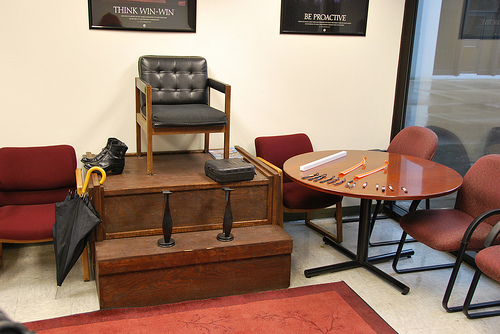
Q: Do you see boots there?
A: Yes, there are boots.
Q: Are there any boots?
A: Yes, there are boots.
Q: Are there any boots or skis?
A: Yes, there are boots.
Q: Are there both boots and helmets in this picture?
A: No, there are boots but no helmets.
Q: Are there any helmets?
A: No, there are no helmets.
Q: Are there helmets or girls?
A: No, there are no helmets or girls.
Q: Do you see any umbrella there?
A: Yes, there is an umbrella.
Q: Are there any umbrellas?
A: Yes, there is an umbrella.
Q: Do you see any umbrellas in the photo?
A: Yes, there is an umbrella.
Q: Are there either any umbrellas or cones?
A: Yes, there is an umbrella.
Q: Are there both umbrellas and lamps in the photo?
A: No, there is an umbrella but no lamps.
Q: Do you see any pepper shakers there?
A: No, there are no pepper shakers.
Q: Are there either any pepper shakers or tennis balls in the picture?
A: No, there are no pepper shakers or tennis balls.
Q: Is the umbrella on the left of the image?
A: Yes, the umbrella is on the left of the image.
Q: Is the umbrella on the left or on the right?
A: The umbrella is on the left of the image.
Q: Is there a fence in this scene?
A: No, there are no fences.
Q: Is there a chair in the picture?
A: Yes, there is a chair.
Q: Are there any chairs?
A: Yes, there is a chair.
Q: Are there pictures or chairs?
A: Yes, there is a chair.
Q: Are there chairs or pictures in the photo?
A: Yes, there is a chair.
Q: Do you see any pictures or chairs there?
A: Yes, there is a chair.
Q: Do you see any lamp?
A: No, there are no lamps.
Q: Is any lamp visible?
A: No, there are no lamps.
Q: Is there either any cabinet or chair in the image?
A: Yes, there is a chair.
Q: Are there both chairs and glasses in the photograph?
A: No, there is a chair but no glasses.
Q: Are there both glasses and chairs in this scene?
A: No, there is a chair but no glasses.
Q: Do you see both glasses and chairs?
A: No, there is a chair but no glasses.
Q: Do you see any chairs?
A: Yes, there is a chair.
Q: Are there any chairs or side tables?
A: Yes, there is a chair.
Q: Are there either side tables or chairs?
A: Yes, there is a chair.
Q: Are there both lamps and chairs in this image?
A: No, there is a chair but no lamps.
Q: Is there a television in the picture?
A: No, there are no televisions.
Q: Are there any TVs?
A: No, there are no tvs.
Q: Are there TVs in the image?
A: No, there are no tvs.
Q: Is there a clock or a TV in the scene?
A: No, there are no televisions or clocks.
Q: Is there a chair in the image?
A: Yes, there is a chair.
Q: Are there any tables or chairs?
A: Yes, there is a chair.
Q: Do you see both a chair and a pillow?
A: No, there is a chair but no pillows.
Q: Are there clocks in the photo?
A: No, there are no clocks.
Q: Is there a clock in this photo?
A: No, there are no clocks.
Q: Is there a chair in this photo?
A: Yes, there is a chair.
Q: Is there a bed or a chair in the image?
A: Yes, there is a chair.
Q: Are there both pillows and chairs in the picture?
A: No, there is a chair but no pillows.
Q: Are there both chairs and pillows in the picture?
A: No, there is a chair but no pillows.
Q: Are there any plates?
A: No, there are no plates.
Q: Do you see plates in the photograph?
A: No, there are no plates.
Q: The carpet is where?
A: The carpet is on the ground.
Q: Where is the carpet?
A: The carpet is on the ground.